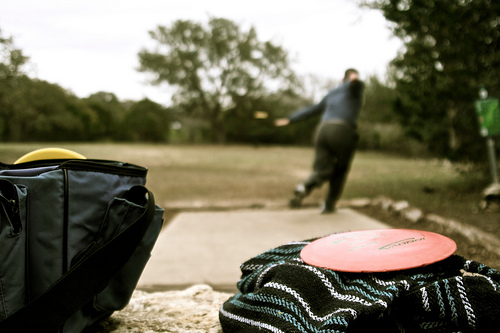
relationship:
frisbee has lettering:
[298, 219, 460, 276] [373, 230, 432, 252]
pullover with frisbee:
[212, 231, 495, 330] [298, 219, 460, 276]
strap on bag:
[2, 182, 168, 332] [0, 157, 164, 332]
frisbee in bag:
[5, 143, 93, 165] [0, 157, 164, 332]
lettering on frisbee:
[373, 230, 432, 252] [298, 219, 460, 276]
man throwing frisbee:
[269, 66, 368, 216] [253, 108, 272, 122]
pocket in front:
[82, 184, 167, 319] [0, 157, 164, 332]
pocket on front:
[82, 184, 167, 319] [0, 157, 164, 332]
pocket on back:
[2, 176, 41, 322] [0, 165, 66, 332]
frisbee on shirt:
[298, 219, 460, 276] [212, 231, 495, 330]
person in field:
[269, 66, 368, 216] [8, 137, 498, 262]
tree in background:
[126, 11, 306, 155] [4, 0, 499, 151]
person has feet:
[269, 66, 368, 216] [286, 181, 343, 219]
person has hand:
[269, 66, 368, 216] [272, 114, 292, 136]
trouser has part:
[289, 120, 359, 216] [310, 121, 359, 156]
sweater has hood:
[212, 231, 495, 330] [218, 261, 391, 331]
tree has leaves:
[126, 11, 306, 155] [140, 53, 179, 80]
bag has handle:
[0, 157, 164, 332] [2, 182, 168, 332]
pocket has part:
[82, 184, 167, 319] [98, 192, 143, 232]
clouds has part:
[9, 1, 401, 109] [17, 5, 52, 27]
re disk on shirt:
[298, 219, 460, 276] [212, 231, 495, 330]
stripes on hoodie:
[228, 282, 347, 332] [212, 231, 495, 330]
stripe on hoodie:
[213, 304, 292, 332] [212, 231, 495, 330]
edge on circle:
[12, 147, 94, 171] [5, 143, 93, 165]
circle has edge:
[5, 143, 93, 165] [12, 147, 94, 171]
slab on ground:
[137, 206, 396, 294] [8, 137, 498, 262]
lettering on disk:
[373, 230, 432, 252] [373, 230, 432, 252]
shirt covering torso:
[290, 79, 369, 126] [320, 85, 361, 133]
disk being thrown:
[253, 108, 272, 122] [256, 112, 273, 124]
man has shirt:
[269, 66, 368, 216] [290, 79, 369, 126]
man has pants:
[269, 66, 368, 216] [289, 120, 359, 216]